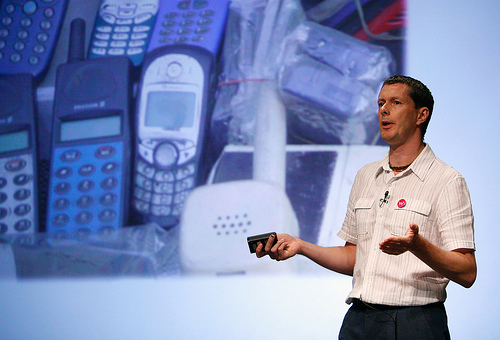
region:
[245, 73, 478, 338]
A man holding a phone.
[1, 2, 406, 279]
A picture of phones on the wall.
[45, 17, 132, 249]
Picture of an old phone.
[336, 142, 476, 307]
A man's company shirt.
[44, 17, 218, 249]
A picture of two old phones.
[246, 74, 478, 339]
A man giving a presentation.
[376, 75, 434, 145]
A man's head and face.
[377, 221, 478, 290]
A hand and arm.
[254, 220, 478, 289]
A pair of arm and hands.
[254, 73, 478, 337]
A man with brown hair.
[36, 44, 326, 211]
picture of cellphones on the wall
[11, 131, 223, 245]
picture of cellphones on the wall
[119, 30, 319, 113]
picture of cellphones on the wall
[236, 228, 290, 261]
Man holding a remote control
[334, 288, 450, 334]
man wearing gray pants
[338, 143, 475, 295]
man wearing a striped shirt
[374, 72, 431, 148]
man with brown hair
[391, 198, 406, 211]
logo on a shirt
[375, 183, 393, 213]
microphone on a shirt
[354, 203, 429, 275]
man with his palm up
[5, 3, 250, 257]
images of cell phones projected on a screen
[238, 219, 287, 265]
small black projector remote control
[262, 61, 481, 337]
man giving a presentation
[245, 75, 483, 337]
man holding a black remote control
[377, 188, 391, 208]
microphone attached to the man's shirt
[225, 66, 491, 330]
man on stage talking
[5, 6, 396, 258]
image projected onto a screen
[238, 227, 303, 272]
man's hand holding the remote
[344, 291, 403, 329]
microphone wire coming out from the man's shirt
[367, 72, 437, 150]
man in the process of talking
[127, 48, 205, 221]
cell phone on slide show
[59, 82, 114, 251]
cell phone on slide show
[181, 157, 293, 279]
cell phone on slide show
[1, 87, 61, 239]
cell phone on slide show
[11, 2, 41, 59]
cell phone on slide show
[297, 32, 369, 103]
cell phone on slide show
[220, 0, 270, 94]
cell phone on slide show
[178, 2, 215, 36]
cell phone on slide show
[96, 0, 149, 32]
cell phone on slide show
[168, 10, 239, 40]
cell phone on slide show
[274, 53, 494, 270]
the man is giving a speech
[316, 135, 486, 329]
the man has a collared shirt on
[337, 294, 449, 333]
the man has black slacks on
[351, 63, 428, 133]
the man has short hair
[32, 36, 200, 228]
these are cell phones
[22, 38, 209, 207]
these phones are old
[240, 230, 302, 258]
the man is holding a remote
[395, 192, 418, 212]
the man has a red badge on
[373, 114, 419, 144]
the man's mouth is open